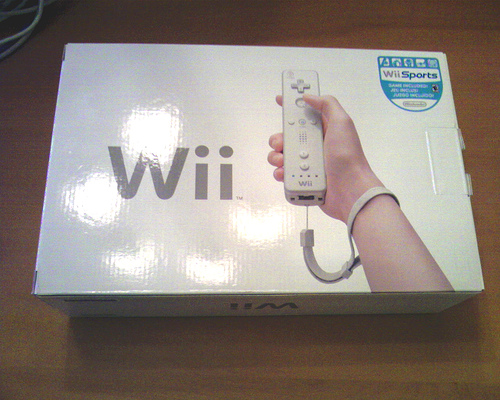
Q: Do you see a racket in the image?
A: No, there are no rackets.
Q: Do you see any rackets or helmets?
A: No, there are no rackets or helmets.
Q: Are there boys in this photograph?
A: No, there are no boys.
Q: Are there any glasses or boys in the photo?
A: No, there are no boys or glasses.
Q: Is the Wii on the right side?
A: Yes, the Wii is on the right of the image.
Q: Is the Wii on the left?
A: No, the Wii is on the right of the image.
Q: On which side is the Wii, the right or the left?
A: The Wii is on the right of the image.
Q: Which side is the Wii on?
A: The Wii is on the right of the image.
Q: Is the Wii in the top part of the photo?
A: Yes, the Wii is in the top of the image.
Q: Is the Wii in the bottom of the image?
A: No, the Wii is in the top of the image.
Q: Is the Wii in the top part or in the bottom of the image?
A: The Wii is in the top of the image.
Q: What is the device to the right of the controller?
A: The device is a Wii.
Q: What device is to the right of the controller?
A: The device is a Wii.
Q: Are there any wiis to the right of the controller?
A: Yes, there is a Wii to the right of the controller.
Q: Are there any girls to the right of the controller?
A: No, there is a Wii to the right of the controller.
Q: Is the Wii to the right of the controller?
A: Yes, the Wii is to the right of the controller.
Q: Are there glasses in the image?
A: No, there are no glasses.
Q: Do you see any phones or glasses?
A: No, there are no glasses or phones.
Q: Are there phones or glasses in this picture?
A: No, there are no glasses or phones.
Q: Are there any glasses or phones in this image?
A: No, there are no glasses or phones.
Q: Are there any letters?
A: Yes, there are letters.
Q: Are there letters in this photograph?
A: Yes, there are letters.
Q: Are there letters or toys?
A: Yes, there are letters.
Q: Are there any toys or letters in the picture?
A: Yes, there are letters.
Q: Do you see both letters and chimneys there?
A: No, there are letters but no chimneys.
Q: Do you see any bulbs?
A: No, there are no bulbs.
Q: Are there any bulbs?
A: No, there are no bulbs.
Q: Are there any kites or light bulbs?
A: No, there are no light bulbs or kites.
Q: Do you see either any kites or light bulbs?
A: No, there are no light bulbs or kites.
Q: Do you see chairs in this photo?
A: No, there are no chairs.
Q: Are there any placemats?
A: No, there are no placemats.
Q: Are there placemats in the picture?
A: No, there are no placemats.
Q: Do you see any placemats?
A: No, there are no placemats.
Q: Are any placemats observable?
A: No, there are no placemats.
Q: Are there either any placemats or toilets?
A: No, there are no placemats or toilets.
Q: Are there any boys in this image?
A: No, there are no boys.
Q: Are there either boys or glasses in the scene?
A: No, there are no boys or glasses.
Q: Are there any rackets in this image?
A: No, there are no rackets.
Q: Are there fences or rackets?
A: No, there are no rackets or fences.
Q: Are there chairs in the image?
A: No, there are no chairs.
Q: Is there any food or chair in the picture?
A: No, there are no chairs or food.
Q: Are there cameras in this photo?
A: No, there are no cameras.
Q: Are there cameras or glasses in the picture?
A: No, there are no cameras or glasses.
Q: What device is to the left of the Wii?
A: The device is a controller.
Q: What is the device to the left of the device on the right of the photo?
A: The device is a controller.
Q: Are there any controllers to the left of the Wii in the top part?
A: Yes, there is a controller to the left of the Wii.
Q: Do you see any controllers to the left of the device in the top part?
A: Yes, there is a controller to the left of the Wii.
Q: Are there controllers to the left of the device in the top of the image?
A: Yes, there is a controller to the left of the Wii.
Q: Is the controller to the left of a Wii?
A: Yes, the controller is to the left of a Wii.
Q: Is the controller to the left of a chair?
A: No, the controller is to the left of a Wii.